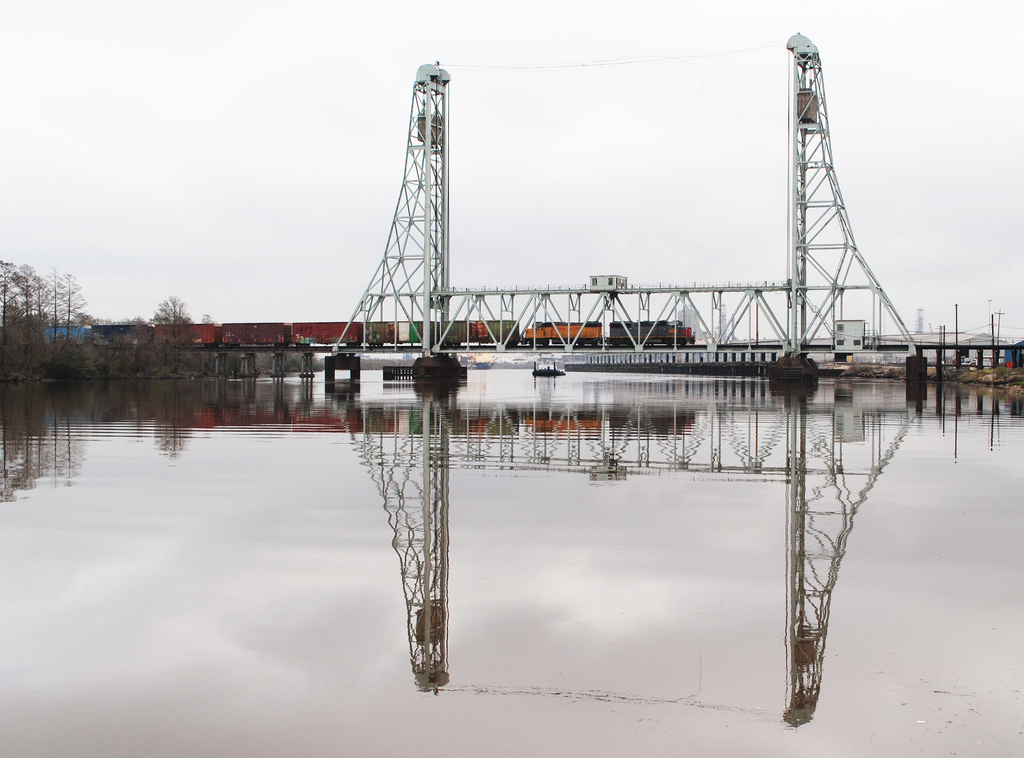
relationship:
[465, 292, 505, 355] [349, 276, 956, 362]
pole on bridge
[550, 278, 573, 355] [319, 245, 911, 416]
pole on bridge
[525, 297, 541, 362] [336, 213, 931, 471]
pole on bridge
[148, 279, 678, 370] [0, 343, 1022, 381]
locomotive on tracks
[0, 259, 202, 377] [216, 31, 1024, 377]
trees next to bridge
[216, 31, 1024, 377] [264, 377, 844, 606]
bridge in water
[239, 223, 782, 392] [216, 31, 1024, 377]
train over bridge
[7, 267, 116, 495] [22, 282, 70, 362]
trees bare of leaves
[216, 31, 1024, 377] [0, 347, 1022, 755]
bridge over lake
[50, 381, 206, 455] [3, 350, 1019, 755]
ripples in water